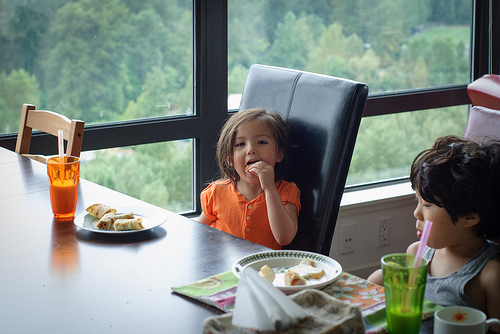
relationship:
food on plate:
[113, 213, 127, 229] [77, 213, 162, 246]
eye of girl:
[236, 138, 253, 145] [195, 103, 300, 222]